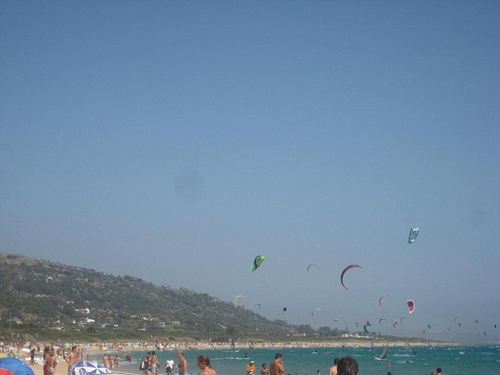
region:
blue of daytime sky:
[3, 1, 498, 333]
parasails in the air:
[231, 225, 497, 355]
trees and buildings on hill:
[3, 250, 454, 346]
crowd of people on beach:
[2, 341, 389, 373]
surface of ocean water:
[91, 343, 498, 373]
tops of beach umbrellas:
[5, 352, 114, 373]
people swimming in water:
[121, 350, 427, 372]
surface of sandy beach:
[3, 344, 104, 371]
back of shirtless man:
[265, 352, 286, 373]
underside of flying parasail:
[404, 299, 416, 313]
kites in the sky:
[223, 212, 498, 350]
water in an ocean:
[381, 349, 489, 365]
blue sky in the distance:
[91, 109, 441, 190]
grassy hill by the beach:
[5, 246, 310, 343]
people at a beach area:
[13, 337, 93, 372]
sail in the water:
[373, 339, 393, 366]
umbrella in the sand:
[4, 338, 39, 373]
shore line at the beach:
[142, 323, 449, 359]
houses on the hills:
[69, 300, 102, 331]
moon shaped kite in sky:
[332, 259, 372, 298]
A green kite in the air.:
[247, 251, 265, 271]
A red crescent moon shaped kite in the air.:
[340, 255, 363, 294]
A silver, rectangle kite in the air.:
[408, 225, 418, 246]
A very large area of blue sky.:
[0, 8, 497, 339]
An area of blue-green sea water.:
[87, 340, 499, 372]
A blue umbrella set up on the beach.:
[0, 355, 34, 373]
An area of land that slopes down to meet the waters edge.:
[0, 250, 434, 341]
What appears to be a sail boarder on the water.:
[375, 342, 391, 360]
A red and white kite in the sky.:
[407, 299, 416, 314]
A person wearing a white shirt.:
[164, 355, 174, 373]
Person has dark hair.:
[330, 355, 357, 372]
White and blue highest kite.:
[408, 223, 420, 243]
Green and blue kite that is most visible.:
[251, 252, 266, 273]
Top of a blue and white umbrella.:
[69, 359, 110, 374]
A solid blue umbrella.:
[0, 354, 35, 374]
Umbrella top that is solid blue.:
[1, 353, 33, 374]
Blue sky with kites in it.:
[1, 1, 499, 343]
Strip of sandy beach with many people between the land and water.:
[3, 338, 473, 348]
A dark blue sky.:
[1, 1, 499, 335]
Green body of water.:
[107, 347, 498, 372]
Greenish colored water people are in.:
[85, 348, 499, 374]